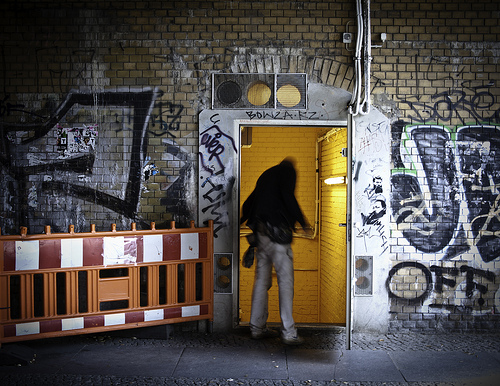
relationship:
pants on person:
[252, 223, 300, 341] [241, 156, 318, 346]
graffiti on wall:
[383, 260, 495, 313] [2, 1, 499, 332]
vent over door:
[277, 72, 307, 112] [238, 124, 348, 327]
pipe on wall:
[364, 0, 374, 118] [2, 1, 499, 332]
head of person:
[275, 156, 297, 169] [241, 156, 318, 346]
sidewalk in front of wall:
[0, 332, 500, 386] [2, 1, 499, 332]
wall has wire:
[2, 1, 499, 332] [353, 1, 361, 116]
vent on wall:
[277, 72, 307, 112] [2, 1, 499, 332]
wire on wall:
[353, 1, 361, 116] [2, 1, 499, 332]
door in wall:
[238, 124, 348, 327] [2, 1, 499, 332]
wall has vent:
[2, 1, 499, 332] [277, 72, 307, 112]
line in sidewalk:
[386, 350, 411, 384] [0, 332, 500, 386]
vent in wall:
[277, 72, 307, 112] [2, 1, 499, 332]